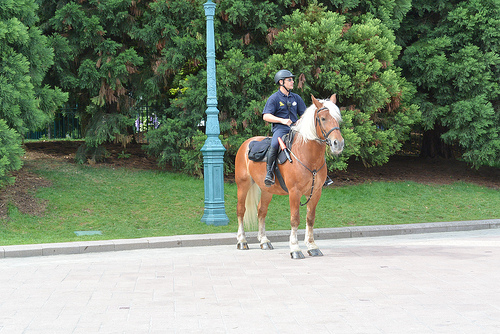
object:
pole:
[198, 1, 231, 228]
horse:
[233, 93, 346, 259]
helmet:
[270, 68, 296, 85]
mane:
[291, 98, 341, 142]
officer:
[259, 68, 309, 188]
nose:
[331, 139, 347, 147]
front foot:
[287, 243, 303, 258]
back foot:
[235, 237, 246, 250]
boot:
[262, 146, 278, 186]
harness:
[310, 105, 342, 140]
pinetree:
[0, 1, 71, 194]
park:
[1, 1, 499, 57]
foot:
[262, 171, 278, 186]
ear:
[308, 94, 321, 110]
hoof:
[306, 247, 321, 256]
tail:
[243, 183, 261, 230]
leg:
[284, 181, 306, 259]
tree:
[54, 0, 151, 165]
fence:
[25, 103, 172, 141]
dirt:
[0, 149, 63, 221]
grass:
[1, 151, 498, 244]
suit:
[261, 91, 308, 131]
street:
[0, 218, 497, 333]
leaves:
[127, 56, 146, 68]